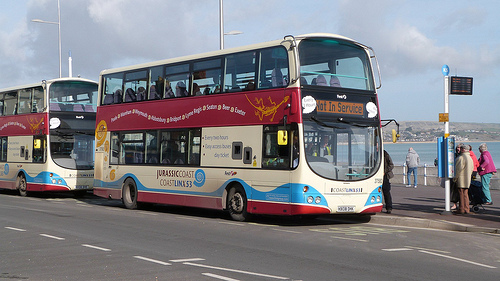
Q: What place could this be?
A: It is a street.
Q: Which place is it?
A: It is a street.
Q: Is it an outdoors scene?
A: Yes, it is outdoors.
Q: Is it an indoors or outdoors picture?
A: It is outdoors.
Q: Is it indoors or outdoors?
A: It is outdoors.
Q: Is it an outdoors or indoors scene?
A: It is outdoors.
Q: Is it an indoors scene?
A: No, it is outdoors.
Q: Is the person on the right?
A: Yes, the person is on the right of the image.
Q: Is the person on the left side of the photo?
A: No, the person is on the right of the image.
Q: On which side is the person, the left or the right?
A: The person is on the right of the image.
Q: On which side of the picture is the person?
A: The person is on the right of the image.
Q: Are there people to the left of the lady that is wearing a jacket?
A: Yes, there is a person to the left of the lady.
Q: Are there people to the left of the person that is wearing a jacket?
A: Yes, there is a person to the left of the lady.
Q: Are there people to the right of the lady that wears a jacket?
A: No, the person is to the left of the lady.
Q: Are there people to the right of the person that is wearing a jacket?
A: No, the person is to the left of the lady.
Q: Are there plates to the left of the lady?
A: No, there is a person to the left of the lady.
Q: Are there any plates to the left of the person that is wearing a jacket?
A: No, there is a person to the left of the lady.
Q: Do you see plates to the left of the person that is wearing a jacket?
A: No, there is a person to the left of the lady.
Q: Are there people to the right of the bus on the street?
A: Yes, there is a person to the right of the bus.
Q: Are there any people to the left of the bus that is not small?
A: No, the person is to the right of the bus.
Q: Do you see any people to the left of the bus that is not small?
A: No, the person is to the right of the bus.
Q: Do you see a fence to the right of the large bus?
A: No, there is a person to the right of the bus.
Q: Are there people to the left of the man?
A: Yes, there is a person to the left of the man.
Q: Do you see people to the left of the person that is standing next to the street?
A: Yes, there is a person to the left of the man.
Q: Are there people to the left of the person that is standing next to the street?
A: Yes, there is a person to the left of the man.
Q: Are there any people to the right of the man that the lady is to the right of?
A: No, the person is to the left of the man.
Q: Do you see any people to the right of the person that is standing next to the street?
A: No, the person is to the left of the man.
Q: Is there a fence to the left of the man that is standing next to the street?
A: No, there is a person to the left of the man.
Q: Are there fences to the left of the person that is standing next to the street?
A: No, there is a person to the left of the man.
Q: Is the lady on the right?
A: Yes, the lady is on the right of the image.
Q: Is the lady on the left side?
A: No, the lady is on the right of the image.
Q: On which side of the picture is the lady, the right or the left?
A: The lady is on the right of the image.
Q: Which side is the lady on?
A: The lady is on the right of the image.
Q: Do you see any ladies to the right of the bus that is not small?
A: Yes, there is a lady to the right of the bus.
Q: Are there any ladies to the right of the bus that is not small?
A: Yes, there is a lady to the right of the bus.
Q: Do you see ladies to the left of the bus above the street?
A: No, the lady is to the right of the bus.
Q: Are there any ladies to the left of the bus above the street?
A: No, the lady is to the right of the bus.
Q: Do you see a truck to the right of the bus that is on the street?
A: No, there is a lady to the right of the bus.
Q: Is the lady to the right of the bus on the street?
A: Yes, the lady is to the right of the bus.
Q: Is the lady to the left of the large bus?
A: No, the lady is to the right of the bus.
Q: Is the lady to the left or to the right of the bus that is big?
A: The lady is to the right of the bus.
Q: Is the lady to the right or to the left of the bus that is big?
A: The lady is to the right of the bus.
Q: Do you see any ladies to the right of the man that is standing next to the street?
A: Yes, there is a lady to the right of the man.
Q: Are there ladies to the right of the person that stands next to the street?
A: Yes, there is a lady to the right of the man.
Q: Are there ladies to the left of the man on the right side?
A: No, the lady is to the right of the man.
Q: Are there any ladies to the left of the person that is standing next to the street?
A: No, the lady is to the right of the man.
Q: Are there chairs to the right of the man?
A: No, there is a lady to the right of the man.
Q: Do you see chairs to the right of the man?
A: No, there is a lady to the right of the man.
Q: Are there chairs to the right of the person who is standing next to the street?
A: No, there is a lady to the right of the man.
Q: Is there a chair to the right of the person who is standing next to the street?
A: No, there is a lady to the right of the man.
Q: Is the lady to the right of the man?
A: Yes, the lady is to the right of the man.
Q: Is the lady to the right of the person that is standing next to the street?
A: Yes, the lady is to the right of the man.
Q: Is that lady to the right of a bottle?
A: No, the lady is to the right of the man.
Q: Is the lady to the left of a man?
A: No, the lady is to the right of a man.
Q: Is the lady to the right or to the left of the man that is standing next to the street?
A: The lady is to the right of the man.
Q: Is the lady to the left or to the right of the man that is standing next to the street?
A: The lady is to the right of the man.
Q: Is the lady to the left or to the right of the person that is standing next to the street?
A: The lady is to the right of the man.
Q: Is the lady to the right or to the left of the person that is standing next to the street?
A: The lady is to the right of the man.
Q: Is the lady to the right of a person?
A: Yes, the lady is to the right of a person.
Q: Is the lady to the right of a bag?
A: No, the lady is to the right of a person.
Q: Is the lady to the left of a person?
A: No, the lady is to the right of a person.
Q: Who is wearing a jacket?
A: The lady is wearing a jacket.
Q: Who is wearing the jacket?
A: The lady is wearing a jacket.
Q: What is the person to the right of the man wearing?
A: The lady is wearing a jacket.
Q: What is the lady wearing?
A: The lady is wearing a jacket.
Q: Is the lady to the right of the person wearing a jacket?
A: Yes, the lady is wearing a jacket.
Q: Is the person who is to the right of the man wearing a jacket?
A: Yes, the lady is wearing a jacket.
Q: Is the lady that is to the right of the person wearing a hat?
A: No, the lady is wearing a jacket.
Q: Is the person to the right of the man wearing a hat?
A: No, the lady is wearing a jacket.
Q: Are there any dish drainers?
A: No, there are no dish drainers.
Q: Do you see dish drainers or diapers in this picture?
A: No, there are no dish drainers or diapers.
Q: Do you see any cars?
A: No, there are no cars.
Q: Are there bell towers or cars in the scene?
A: No, there are no cars or bell towers.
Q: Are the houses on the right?
A: Yes, the houses are on the right of the image.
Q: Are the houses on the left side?
A: No, the houses are on the right of the image.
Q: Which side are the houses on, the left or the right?
A: The houses are on the right of the image.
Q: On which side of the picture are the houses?
A: The houses are on the right of the image.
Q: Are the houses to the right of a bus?
A: Yes, the houses are to the right of a bus.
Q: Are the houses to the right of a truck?
A: No, the houses are to the right of a bus.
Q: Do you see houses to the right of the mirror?
A: Yes, there are houses to the right of the mirror.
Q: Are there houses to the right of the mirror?
A: Yes, there are houses to the right of the mirror.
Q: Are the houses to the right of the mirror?
A: Yes, the houses are to the right of the mirror.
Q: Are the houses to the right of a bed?
A: No, the houses are to the right of the mirror.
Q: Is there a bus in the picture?
A: Yes, there is a bus.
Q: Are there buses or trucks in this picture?
A: Yes, there is a bus.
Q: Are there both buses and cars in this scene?
A: No, there is a bus but no cars.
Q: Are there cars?
A: No, there are no cars.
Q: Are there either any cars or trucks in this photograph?
A: No, there are no cars or trucks.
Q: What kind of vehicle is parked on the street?
A: The vehicle is a bus.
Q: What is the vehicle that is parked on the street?
A: The vehicle is a bus.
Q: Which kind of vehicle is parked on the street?
A: The vehicle is a bus.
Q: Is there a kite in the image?
A: No, there are no kites.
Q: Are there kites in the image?
A: No, there are no kites.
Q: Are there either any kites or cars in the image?
A: No, there are no kites or cars.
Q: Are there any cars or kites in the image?
A: No, there are no kites or cars.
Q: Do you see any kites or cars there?
A: No, there are no kites or cars.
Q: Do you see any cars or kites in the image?
A: No, there are no kites or cars.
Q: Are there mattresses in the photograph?
A: No, there are no mattresses.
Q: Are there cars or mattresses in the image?
A: No, there are no mattresses or cars.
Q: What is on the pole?
A: The sign is on the pole.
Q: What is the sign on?
A: The sign is on the pole.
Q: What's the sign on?
A: The sign is on the pole.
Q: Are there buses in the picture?
A: Yes, there is a bus.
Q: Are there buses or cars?
A: Yes, there is a bus.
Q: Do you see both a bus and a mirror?
A: Yes, there are both a bus and a mirror.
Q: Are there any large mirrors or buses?
A: Yes, there is a large bus.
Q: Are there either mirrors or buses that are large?
A: Yes, the bus is large.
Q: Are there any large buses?
A: Yes, there is a large bus.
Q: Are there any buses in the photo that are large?
A: Yes, there is a bus that is large.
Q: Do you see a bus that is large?
A: Yes, there is a bus that is large.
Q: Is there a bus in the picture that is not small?
A: Yes, there is a large bus.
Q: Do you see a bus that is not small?
A: Yes, there is a large bus.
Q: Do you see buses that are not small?
A: Yes, there is a large bus.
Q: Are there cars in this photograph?
A: No, there are no cars.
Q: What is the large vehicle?
A: The vehicle is a bus.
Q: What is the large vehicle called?
A: The vehicle is a bus.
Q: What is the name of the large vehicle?
A: The vehicle is a bus.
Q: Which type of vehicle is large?
A: The vehicle is a bus.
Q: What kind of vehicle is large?
A: The vehicle is a bus.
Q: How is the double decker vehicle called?
A: The vehicle is a bus.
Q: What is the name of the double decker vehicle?
A: The vehicle is a bus.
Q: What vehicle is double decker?
A: The vehicle is a bus.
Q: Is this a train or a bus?
A: This is a bus.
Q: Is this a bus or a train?
A: This is a bus.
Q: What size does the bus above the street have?
A: The bus has large size.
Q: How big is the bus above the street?
A: The bus is large.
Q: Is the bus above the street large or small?
A: The bus is large.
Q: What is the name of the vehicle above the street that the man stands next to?
A: The vehicle is a bus.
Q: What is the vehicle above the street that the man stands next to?
A: The vehicle is a bus.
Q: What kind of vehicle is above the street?
A: The vehicle is a bus.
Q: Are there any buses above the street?
A: Yes, there is a bus above the street.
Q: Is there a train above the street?
A: No, there is a bus above the street.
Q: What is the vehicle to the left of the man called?
A: The vehicle is a bus.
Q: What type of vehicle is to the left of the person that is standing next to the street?
A: The vehicle is a bus.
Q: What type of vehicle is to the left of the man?
A: The vehicle is a bus.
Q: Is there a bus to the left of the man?
A: Yes, there is a bus to the left of the man.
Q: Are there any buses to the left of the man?
A: Yes, there is a bus to the left of the man.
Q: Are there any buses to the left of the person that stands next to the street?
A: Yes, there is a bus to the left of the man.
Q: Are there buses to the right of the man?
A: No, the bus is to the left of the man.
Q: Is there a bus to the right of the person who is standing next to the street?
A: No, the bus is to the left of the man.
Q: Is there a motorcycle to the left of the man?
A: No, there is a bus to the left of the man.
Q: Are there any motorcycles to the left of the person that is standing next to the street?
A: No, there is a bus to the left of the man.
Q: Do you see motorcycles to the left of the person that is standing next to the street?
A: No, there is a bus to the left of the man.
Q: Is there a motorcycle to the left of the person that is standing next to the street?
A: No, there is a bus to the left of the man.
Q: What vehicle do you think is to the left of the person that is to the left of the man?
A: The vehicle is a bus.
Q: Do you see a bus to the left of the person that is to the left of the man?
A: Yes, there is a bus to the left of the person.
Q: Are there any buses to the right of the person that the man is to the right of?
A: No, the bus is to the left of the person.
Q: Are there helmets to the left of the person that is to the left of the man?
A: No, there is a bus to the left of the person.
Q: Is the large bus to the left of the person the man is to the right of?
A: Yes, the bus is to the left of the person.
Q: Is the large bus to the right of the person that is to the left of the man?
A: No, the bus is to the left of the person.